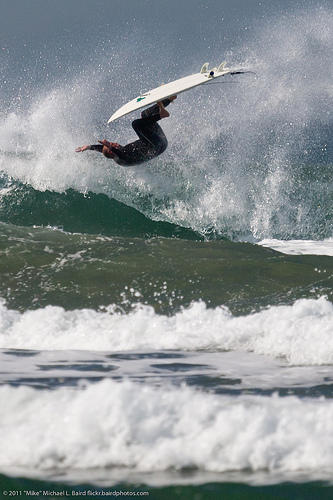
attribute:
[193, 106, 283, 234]
crashing wave — large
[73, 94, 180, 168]
surfboarder — upside down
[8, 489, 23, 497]
stamp — numerical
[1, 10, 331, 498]
water — green, blue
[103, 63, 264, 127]
surfboard — upside down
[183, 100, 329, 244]
wave — rolling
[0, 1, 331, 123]
sky — blue, clear blue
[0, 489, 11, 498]
symbol — white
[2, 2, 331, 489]
beach scene — daytime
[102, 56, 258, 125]
surfboard — white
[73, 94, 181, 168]
wet suit — black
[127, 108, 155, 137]
knees — bent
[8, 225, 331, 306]
waves — sea green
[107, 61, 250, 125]
surfboard — upside down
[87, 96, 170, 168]
wetsuit — black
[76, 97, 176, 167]
surfer — bald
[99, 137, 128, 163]
arm — outstretched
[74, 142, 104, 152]
arm — outstretched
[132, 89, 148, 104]
design — green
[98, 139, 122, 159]
head — bald